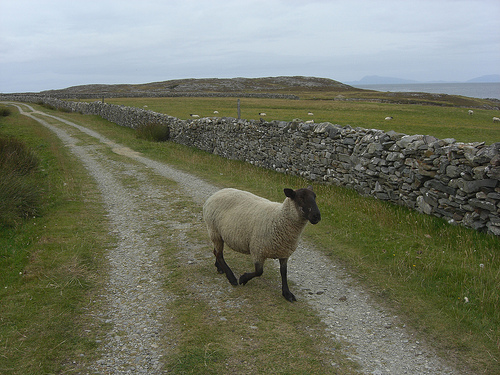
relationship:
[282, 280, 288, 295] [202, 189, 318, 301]
black foot sheep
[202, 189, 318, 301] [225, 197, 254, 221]
sheep with white fur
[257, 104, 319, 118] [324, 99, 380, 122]
sheep in field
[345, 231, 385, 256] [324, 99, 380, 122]
green grass in field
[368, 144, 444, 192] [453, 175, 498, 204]
wall made of rocks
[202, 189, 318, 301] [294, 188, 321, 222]
sheep has black face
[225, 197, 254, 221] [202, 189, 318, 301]
fur of sheep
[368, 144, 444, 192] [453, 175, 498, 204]
wall of rocks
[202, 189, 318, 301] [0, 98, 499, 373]
sheep on road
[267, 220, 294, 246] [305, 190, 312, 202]
white and brown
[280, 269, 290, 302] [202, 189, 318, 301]
leg of sheep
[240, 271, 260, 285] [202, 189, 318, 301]
leg of sheep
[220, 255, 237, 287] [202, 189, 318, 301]
leg of sheep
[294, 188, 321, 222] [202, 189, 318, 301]
head of sheep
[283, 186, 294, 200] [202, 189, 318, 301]
ear of sheep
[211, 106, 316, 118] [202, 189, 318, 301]
flock of sheep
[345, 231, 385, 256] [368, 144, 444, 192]
green bush near wall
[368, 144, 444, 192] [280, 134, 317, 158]
wall made of stone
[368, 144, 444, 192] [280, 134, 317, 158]
wall of stone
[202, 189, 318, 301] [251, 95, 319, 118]
sheep in pasture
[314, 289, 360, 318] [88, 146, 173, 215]
dirt on road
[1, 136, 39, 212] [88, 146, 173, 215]
bushes near road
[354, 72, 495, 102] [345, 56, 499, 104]
mountains in distance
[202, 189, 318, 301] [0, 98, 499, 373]
sheep walking on road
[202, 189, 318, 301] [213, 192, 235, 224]
sheep has wool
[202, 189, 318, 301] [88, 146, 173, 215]
sheep on road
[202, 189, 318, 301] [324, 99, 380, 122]
sheep on field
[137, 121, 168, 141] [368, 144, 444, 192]
bush near wall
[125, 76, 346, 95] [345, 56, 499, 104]
hills in distance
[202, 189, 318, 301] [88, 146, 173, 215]
sheep in road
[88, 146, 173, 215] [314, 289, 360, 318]
road made of dirt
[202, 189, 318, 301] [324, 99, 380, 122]
sheep in field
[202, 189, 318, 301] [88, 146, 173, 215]
sheep walking on road